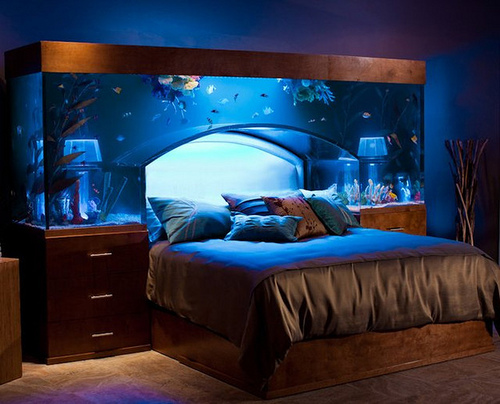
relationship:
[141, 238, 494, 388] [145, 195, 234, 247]
bed has pillow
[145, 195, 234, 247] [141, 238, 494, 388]
pillow are on bed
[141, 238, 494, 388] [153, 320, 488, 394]
bed on frame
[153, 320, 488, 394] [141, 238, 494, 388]
frame under bed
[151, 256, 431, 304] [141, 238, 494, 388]
blanket on bed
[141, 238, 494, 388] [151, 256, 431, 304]
bed under blanket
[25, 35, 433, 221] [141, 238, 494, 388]
aquarium above bed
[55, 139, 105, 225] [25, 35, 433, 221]
left lamp behind aquarium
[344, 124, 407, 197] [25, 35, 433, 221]
right lamp behind aquarium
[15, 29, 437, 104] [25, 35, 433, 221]
wood on top of aquarium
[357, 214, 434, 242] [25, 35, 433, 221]
right drawers are underneath aquarium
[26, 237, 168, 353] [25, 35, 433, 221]
left drawers are underneath aquarium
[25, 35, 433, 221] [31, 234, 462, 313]
aquarium on drawers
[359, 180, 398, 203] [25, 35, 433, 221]
coral in aquarium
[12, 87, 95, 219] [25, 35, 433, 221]
plants in aquarium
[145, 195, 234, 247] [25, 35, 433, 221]
pillow are under aquarium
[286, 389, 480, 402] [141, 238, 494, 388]
carpet under bed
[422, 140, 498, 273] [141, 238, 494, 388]
plant next to bed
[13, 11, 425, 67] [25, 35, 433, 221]
wall behind aquarium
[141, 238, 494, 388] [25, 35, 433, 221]
bed in front of aquarium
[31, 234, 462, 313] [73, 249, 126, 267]
drawers have handles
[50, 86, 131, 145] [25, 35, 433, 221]
water in aquarium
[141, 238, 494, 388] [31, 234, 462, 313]
bed next to drawers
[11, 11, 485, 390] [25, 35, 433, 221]
bedroom has aquarium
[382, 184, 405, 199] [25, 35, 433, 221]
fish in aquarium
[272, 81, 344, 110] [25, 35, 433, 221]
coral near top of aquarium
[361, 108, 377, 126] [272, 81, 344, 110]
fish near coral